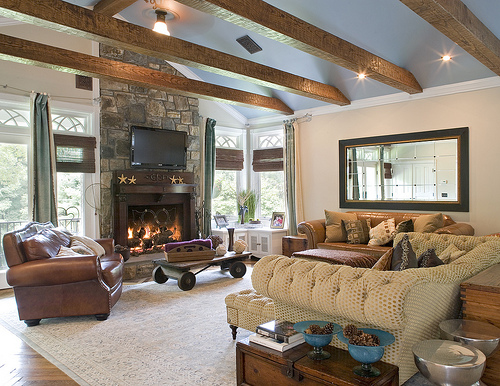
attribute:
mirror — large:
[331, 125, 473, 215]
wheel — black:
[229, 262, 254, 274]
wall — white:
[291, 86, 498, 293]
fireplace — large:
[117, 187, 199, 242]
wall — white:
[306, 125, 331, 185]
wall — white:
[308, 128, 329, 175]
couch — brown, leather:
[288, 197, 474, 257]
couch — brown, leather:
[294, 210, 472, 260]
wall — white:
[300, 87, 498, 231]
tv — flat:
[127, 119, 189, 171]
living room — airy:
[29, 137, 481, 342]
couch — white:
[223, 225, 497, 380]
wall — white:
[269, 87, 494, 270]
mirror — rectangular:
[334, 137, 473, 207]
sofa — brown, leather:
[298, 208, 468, 263]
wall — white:
[174, 79, 249, 132]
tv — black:
[124, 120, 191, 172]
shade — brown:
[248, 145, 288, 174]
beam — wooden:
[1, 32, 297, 114]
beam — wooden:
[2, 0, 350, 106]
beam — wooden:
[173, 1, 423, 95]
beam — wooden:
[399, 0, 499, 75]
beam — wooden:
[90, 0, 132, 17]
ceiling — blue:
[67, 1, 497, 121]